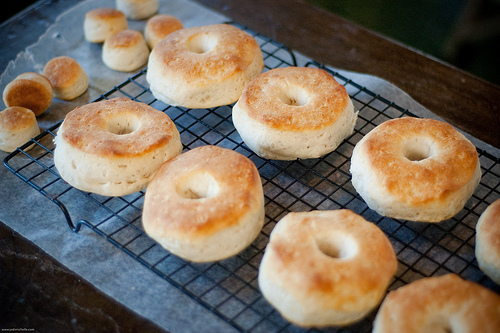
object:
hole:
[189, 37, 215, 54]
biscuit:
[145, 23, 264, 109]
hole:
[278, 86, 309, 106]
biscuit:
[231, 66, 359, 161]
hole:
[401, 142, 434, 162]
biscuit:
[350, 116, 483, 223]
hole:
[101, 113, 141, 137]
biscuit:
[52, 98, 184, 199]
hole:
[174, 173, 220, 201]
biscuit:
[142, 144, 265, 263]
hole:
[314, 230, 360, 259]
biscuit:
[256, 207, 397, 327]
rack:
[2, 21, 500, 332]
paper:
[0, 0, 499, 332]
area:
[0, 0, 499, 333]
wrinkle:
[64, 23, 480, 282]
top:
[151, 23, 259, 80]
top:
[240, 66, 348, 133]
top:
[360, 117, 478, 207]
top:
[62, 97, 174, 158]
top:
[142, 144, 258, 239]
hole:
[54, 31, 62, 39]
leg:
[54, 201, 88, 233]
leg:
[285, 42, 318, 67]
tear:
[11, 47, 47, 74]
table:
[1, 0, 498, 332]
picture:
[1, 0, 499, 332]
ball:
[1, 105, 41, 154]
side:
[0, 0, 236, 156]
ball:
[0, 70, 53, 117]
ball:
[40, 56, 89, 101]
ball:
[100, 26, 150, 72]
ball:
[83, 8, 127, 41]